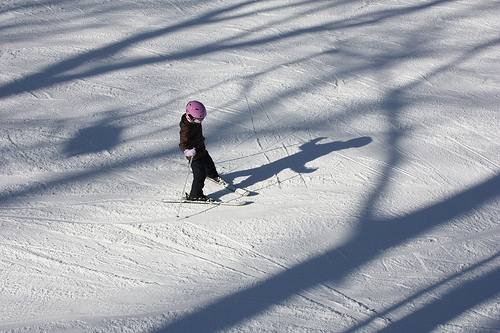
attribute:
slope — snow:
[19, 31, 151, 292]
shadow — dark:
[238, 130, 376, 201]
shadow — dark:
[4, 2, 98, 48]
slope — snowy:
[8, 6, 139, 172]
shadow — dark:
[219, 133, 372, 201]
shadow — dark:
[58, 115, 120, 157]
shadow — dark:
[2, 40, 497, 213]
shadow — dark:
[142, 72, 499, 330]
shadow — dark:
[342, 240, 497, 332]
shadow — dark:
[60, 120, 130, 166]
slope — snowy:
[4, 8, 477, 329]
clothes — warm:
[173, 111, 223, 191]